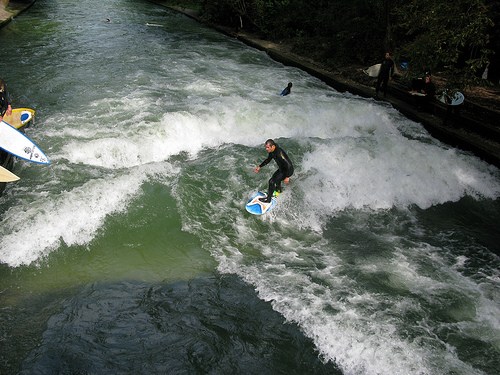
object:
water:
[36, 222, 421, 371]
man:
[252, 137, 296, 205]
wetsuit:
[256, 152, 293, 199]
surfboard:
[243, 176, 291, 218]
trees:
[413, 0, 489, 78]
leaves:
[431, 18, 457, 45]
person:
[372, 51, 398, 95]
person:
[417, 73, 439, 118]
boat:
[0, 107, 38, 135]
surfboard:
[0, 119, 52, 169]